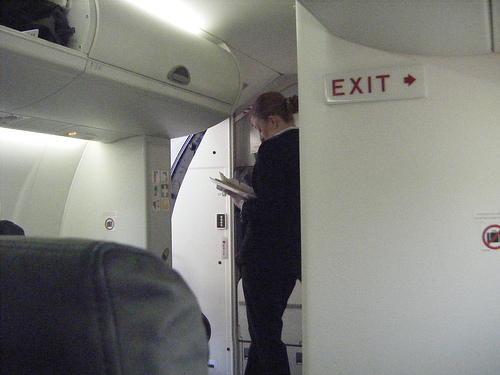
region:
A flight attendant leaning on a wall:
[232, 89, 308, 374]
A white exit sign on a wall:
[323, 61, 427, 104]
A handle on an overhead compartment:
[167, 60, 194, 87]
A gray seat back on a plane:
[2, 229, 212, 374]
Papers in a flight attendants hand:
[208, 170, 254, 205]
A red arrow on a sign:
[402, 70, 419, 86]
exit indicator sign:
[321, 64, 432, 106]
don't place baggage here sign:
[468, 208, 499, 251]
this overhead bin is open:
[0, 0, 107, 80]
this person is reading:
[213, 86, 302, 373]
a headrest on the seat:
[0, 232, 214, 374]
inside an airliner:
[1, 96, 498, 373]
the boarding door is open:
[156, 110, 234, 374]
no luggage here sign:
[99, 213, 119, 234]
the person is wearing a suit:
[225, 95, 304, 373]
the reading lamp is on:
[64, 128, 79, 138]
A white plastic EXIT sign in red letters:
[315, 65, 429, 104]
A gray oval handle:
[165, 58, 197, 90]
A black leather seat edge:
[7, 228, 215, 364]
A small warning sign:
[152, 169, 171, 210]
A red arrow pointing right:
[397, 69, 417, 90]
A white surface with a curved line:
[47, 148, 102, 199]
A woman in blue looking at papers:
[215, 90, 302, 372]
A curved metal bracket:
[173, 141, 198, 204]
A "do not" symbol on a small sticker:
[480, 210, 498, 256]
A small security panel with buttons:
[214, 204, 231, 234]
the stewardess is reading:
[210, 77, 311, 256]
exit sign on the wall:
[310, 47, 441, 126]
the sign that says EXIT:
[324, 65, 426, 100]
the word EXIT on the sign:
[325, 63, 427, 101]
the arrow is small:
[402, 72, 414, 86]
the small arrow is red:
[401, 71, 415, 86]